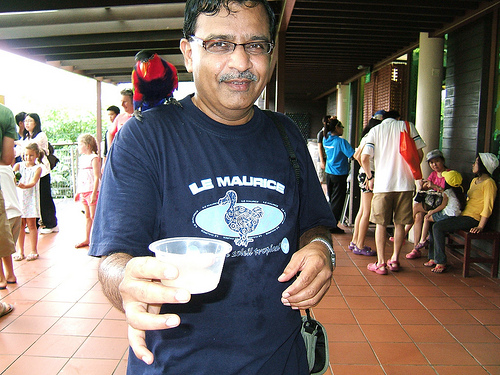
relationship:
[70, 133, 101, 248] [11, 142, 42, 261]
person next person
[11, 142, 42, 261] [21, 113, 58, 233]
person next person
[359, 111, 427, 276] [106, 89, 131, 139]
people next person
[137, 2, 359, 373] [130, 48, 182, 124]
man have bird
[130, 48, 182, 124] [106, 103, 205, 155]
bird on shoulder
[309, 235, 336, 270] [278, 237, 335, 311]
watch on hand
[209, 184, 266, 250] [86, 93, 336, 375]
duck image on blue shirt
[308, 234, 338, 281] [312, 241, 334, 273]
watch on wrist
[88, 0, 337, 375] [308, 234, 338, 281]
man has watch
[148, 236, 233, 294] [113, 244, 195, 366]
container in hand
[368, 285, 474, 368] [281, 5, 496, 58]
floor under ceiling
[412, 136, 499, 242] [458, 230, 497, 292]
people on bench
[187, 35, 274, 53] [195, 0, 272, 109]
glasses on face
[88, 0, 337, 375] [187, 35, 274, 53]
man has glasses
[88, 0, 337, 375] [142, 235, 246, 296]
man holds cup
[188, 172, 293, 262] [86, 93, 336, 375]
white graphic on blue shirt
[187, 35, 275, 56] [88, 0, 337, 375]
glasses on man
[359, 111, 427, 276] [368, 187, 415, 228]
people wears shorts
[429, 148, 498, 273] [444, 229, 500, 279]
person on bench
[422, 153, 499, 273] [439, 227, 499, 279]
people on chair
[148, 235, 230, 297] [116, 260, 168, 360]
container in hand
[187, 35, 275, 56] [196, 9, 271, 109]
glasses on face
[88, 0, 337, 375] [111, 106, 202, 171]
man on shoulder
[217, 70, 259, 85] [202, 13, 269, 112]
moustache on face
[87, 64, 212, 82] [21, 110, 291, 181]
beams of ceiling